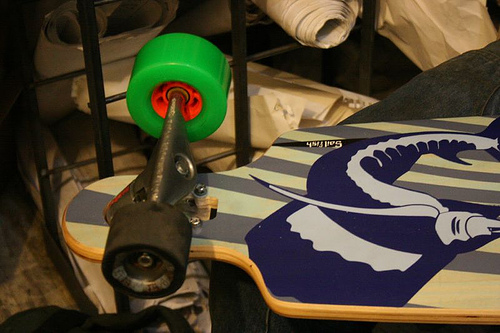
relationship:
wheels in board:
[126, 31, 236, 138] [52, 117, 499, 320]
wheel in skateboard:
[98, 193, 243, 325] [25, 50, 485, 329]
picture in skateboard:
[247, 132, 499, 300] [53, 29, 498, 327]